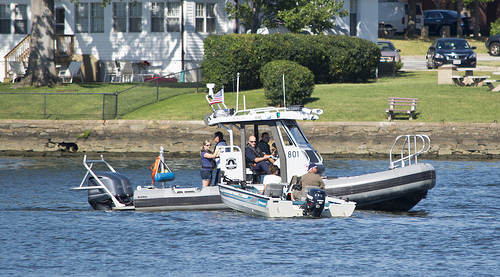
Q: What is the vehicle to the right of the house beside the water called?
A: The vehicle is a car.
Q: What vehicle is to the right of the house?
A: The vehicle is a car.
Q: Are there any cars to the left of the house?
A: No, the car is to the right of the house.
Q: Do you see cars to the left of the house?
A: No, the car is to the right of the house.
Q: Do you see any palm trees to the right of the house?
A: No, there is a car to the right of the house.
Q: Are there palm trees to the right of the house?
A: No, there is a car to the right of the house.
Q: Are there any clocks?
A: No, there are no clocks.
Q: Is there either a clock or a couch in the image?
A: No, there are no clocks or couches.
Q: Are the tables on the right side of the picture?
A: Yes, the tables are on the right of the image.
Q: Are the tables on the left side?
A: No, the tables are on the right of the image.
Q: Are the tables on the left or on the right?
A: The tables are on the right of the image.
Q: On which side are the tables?
A: The tables are on the right of the image.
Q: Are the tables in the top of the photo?
A: Yes, the tables are in the top of the image.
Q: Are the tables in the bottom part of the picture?
A: No, the tables are in the top of the image.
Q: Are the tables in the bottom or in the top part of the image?
A: The tables are in the top of the image.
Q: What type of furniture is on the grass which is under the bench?
A: The pieces of furniture are tables.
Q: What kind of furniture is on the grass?
A: The pieces of furniture are tables.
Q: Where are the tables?
A: The tables are on the grass.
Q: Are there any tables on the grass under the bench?
A: Yes, there are tables on the grass.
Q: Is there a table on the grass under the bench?
A: Yes, there are tables on the grass.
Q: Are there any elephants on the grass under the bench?
A: No, there are tables on the grass.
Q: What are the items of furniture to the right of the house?
A: The pieces of furniture are tables.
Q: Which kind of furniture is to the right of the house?
A: The pieces of furniture are tables.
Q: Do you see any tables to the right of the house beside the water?
A: Yes, there are tables to the right of the house.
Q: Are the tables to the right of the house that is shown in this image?
A: Yes, the tables are to the right of the house.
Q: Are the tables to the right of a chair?
A: No, the tables are to the right of the house.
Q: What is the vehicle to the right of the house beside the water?
A: The vehicle is a car.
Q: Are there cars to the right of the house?
A: Yes, there is a car to the right of the house.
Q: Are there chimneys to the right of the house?
A: No, there is a car to the right of the house.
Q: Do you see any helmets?
A: No, there are no helmets.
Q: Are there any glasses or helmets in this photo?
A: No, there are no helmets or glasses.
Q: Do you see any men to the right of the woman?
A: Yes, there is a man to the right of the woman.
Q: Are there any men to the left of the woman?
A: No, the man is to the right of the woman.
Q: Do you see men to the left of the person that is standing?
A: No, the man is to the right of the woman.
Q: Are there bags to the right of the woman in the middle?
A: No, there is a man to the right of the woman.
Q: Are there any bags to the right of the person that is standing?
A: No, there is a man to the right of the woman.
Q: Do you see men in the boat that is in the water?
A: Yes, there is a man in the boat.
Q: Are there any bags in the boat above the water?
A: No, there is a man in the boat.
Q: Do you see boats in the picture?
A: Yes, there is a boat.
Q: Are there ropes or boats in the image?
A: Yes, there is a boat.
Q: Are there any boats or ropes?
A: Yes, there is a boat.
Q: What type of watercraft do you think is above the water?
A: The watercraft is a boat.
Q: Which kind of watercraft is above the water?
A: The watercraft is a boat.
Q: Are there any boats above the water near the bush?
A: Yes, there is a boat above the water.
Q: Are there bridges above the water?
A: No, there is a boat above the water.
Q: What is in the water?
A: The boat is in the water.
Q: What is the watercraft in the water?
A: The watercraft is a boat.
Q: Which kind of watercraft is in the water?
A: The watercraft is a boat.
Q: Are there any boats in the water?
A: Yes, there is a boat in the water.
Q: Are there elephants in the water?
A: No, there is a boat in the water.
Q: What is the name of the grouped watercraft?
A: The watercraft is boats.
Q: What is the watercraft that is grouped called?
A: The watercraft is boats.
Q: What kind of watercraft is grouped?
A: The watercraft is boats.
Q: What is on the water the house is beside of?
A: The boats are on the water.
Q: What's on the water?
A: The boats are on the water.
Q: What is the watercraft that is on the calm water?
A: The watercraft is boats.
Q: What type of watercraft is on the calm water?
A: The watercraft is boats.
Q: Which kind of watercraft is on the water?
A: The watercraft is boats.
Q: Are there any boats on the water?
A: Yes, there are boats on the water.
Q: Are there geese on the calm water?
A: No, there are boats on the water.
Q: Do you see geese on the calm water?
A: No, there are boats on the water.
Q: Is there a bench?
A: Yes, there is a bench.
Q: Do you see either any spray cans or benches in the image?
A: Yes, there is a bench.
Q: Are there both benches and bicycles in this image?
A: No, there is a bench but no bicycles.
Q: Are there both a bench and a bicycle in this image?
A: No, there is a bench but no bicycles.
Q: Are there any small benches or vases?
A: Yes, there is a small bench.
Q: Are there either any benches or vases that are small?
A: Yes, the bench is small.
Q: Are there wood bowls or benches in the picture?
A: Yes, there is a wood bench.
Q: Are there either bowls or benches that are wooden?
A: Yes, the bench is wooden.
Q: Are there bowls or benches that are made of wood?
A: Yes, the bench is made of wood.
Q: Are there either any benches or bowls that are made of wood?
A: Yes, the bench is made of wood.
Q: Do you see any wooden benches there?
A: Yes, there is a wood bench.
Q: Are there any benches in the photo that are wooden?
A: Yes, there is a bench that is wooden.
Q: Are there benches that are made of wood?
A: Yes, there is a bench that is made of wood.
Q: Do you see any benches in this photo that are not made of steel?
A: Yes, there is a bench that is made of wood.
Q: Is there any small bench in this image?
A: Yes, there is a small bench.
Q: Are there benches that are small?
A: Yes, there is a bench that is small.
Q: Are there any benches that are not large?
A: Yes, there is a small bench.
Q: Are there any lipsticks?
A: No, there are no lipsticks.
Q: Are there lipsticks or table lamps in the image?
A: No, there are no lipsticks or table lamps.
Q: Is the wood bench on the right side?
A: Yes, the bench is on the right of the image.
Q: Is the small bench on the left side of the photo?
A: No, the bench is on the right of the image.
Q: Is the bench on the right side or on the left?
A: The bench is on the right of the image.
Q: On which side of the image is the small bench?
A: The bench is on the right of the image.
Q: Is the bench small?
A: Yes, the bench is small.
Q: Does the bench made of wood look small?
A: Yes, the bench is small.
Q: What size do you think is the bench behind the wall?
A: The bench is small.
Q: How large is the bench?
A: The bench is small.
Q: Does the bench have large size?
A: No, the bench is small.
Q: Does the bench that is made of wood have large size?
A: No, the bench is small.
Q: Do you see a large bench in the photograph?
A: No, there is a bench but it is small.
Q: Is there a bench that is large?
A: No, there is a bench but it is small.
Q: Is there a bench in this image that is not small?
A: No, there is a bench but it is small.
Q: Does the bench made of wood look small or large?
A: The bench is small.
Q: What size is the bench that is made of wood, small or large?
A: The bench is small.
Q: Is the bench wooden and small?
A: Yes, the bench is wooden and small.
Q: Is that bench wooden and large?
A: No, the bench is wooden but small.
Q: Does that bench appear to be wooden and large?
A: No, the bench is wooden but small.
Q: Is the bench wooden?
A: Yes, the bench is wooden.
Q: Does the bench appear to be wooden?
A: Yes, the bench is wooden.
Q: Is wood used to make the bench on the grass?
A: Yes, the bench is made of wood.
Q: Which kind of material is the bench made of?
A: The bench is made of wood.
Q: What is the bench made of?
A: The bench is made of wood.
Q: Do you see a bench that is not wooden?
A: No, there is a bench but it is wooden.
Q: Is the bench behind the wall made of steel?
A: No, the bench is made of wood.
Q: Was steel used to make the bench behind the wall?
A: No, the bench is made of wood.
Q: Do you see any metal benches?
A: No, there is a bench but it is made of wood.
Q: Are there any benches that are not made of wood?
A: No, there is a bench but it is made of wood.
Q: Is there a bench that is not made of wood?
A: No, there is a bench but it is made of wood.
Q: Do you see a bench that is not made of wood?
A: No, there is a bench but it is made of wood.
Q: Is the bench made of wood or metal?
A: The bench is made of wood.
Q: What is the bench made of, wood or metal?
A: The bench is made of wood.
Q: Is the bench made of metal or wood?
A: The bench is made of wood.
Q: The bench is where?
A: The bench is on the grass.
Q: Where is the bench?
A: The bench is on the grass.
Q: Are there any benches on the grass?
A: Yes, there is a bench on the grass.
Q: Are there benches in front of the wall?
A: No, the bench is behind the wall.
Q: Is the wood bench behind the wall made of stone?
A: Yes, the bench is behind the wall.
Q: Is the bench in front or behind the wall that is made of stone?
A: The bench is behind the wall.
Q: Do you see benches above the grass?
A: Yes, there is a bench above the grass.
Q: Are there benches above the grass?
A: Yes, there is a bench above the grass.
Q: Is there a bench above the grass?
A: Yes, there is a bench above the grass.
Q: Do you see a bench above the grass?
A: Yes, there is a bench above the grass.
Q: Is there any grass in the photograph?
A: Yes, there is grass.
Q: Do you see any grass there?
A: Yes, there is grass.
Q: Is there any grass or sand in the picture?
A: Yes, there is grass.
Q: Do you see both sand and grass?
A: No, there is grass but no sand.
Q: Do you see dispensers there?
A: No, there are no dispensers.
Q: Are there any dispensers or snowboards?
A: No, there are no dispensers or snowboards.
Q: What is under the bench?
A: The grass is under the bench.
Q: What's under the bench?
A: The grass is under the bench.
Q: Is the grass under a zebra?
A: No, the grass is under the bench.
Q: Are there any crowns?
A: No, there are no crowns.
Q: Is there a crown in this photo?
A: No, there are no crowns.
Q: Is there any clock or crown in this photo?
A: No, there are no crowns or clocks.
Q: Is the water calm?
A: Yes, the water is calm.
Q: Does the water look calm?
A: Yes, the water is calm.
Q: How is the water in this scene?
A: The water is calm.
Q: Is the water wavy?
A: No, the water is calm.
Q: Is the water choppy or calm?
A: The water is calm.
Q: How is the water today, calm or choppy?
A: The water is calm.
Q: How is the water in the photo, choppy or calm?
A: The water is calm.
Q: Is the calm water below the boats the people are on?
A: Yes, the water is below the boats.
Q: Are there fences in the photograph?
A: Yes, there is a fence.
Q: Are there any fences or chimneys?
A: Yes, there is a fence.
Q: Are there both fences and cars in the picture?
A: Yes, there are both a fence and a car.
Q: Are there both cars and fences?
A: Yes, there are both a fence and a car.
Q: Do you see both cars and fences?
A: Yes, there are both a fence and a car.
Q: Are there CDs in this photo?
A: No, there are no cds.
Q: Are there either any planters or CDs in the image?
A: No, there are no CDs or planters.